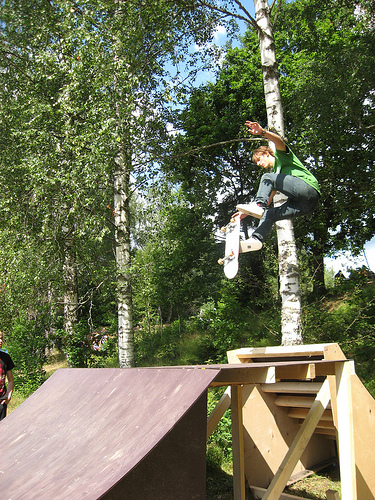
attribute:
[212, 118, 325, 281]
skateboarder — airborne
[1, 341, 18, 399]
t-shirt — black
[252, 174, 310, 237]
jeans — blue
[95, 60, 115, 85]
leaves — green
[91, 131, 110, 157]
leaves — green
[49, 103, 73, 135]
leaves — green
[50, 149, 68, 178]
leaves — green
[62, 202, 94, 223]
leaves — green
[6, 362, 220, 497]
ramp — wooden, skateboard ramp, purple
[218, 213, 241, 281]
skateboard — airborne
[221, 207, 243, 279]
skateboard — airborne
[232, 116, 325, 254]
boy — airborne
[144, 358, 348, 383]
platform — wooden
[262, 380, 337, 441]
steps — wooden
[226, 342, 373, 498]
ramp — skateboard ramp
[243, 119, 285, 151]
arm — extended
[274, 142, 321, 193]
shirt — green